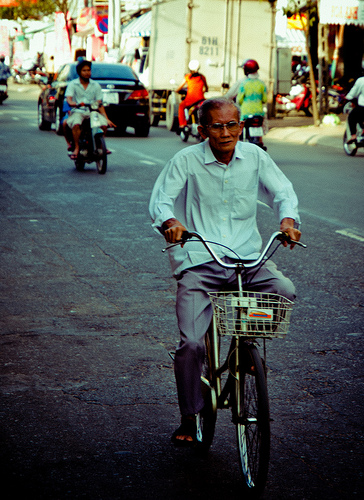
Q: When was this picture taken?
A: Daytime.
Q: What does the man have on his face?
A: Glasses.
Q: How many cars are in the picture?
A: 1.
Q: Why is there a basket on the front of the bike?
A: To hold things.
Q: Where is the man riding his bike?
A: Street.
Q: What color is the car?
A: Black.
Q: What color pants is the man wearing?
A: Grey.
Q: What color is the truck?
A: White.